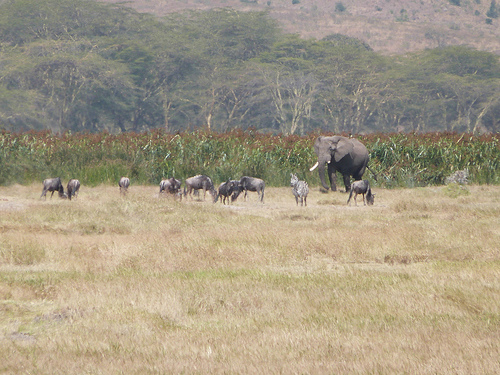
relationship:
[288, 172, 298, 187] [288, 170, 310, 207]
head on zebra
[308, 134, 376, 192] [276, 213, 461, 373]
elephant on grass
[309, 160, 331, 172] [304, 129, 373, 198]
tusk on elephant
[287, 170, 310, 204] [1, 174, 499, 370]
zebra in grass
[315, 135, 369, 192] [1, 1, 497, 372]
elephant on savanna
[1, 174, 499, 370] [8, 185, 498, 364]
grass in field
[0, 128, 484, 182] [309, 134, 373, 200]
plants behind elephant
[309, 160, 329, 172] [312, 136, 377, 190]
tusk on elephant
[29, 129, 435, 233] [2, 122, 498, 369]
animals in field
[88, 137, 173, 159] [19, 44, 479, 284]
corn in field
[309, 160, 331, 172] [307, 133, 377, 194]
tusk on elephant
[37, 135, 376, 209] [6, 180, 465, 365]
animals in grass